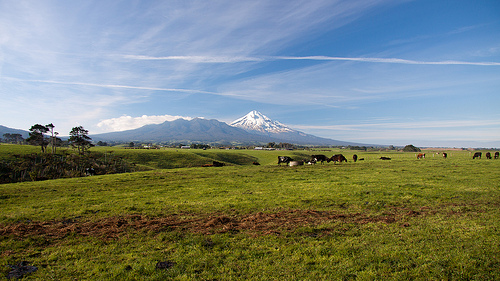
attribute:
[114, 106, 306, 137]
mountain — background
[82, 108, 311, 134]
mountain —  snow capped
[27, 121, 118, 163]
trees — background, Tall 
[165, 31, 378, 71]
clouds — Light colored , sky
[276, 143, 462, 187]
animals —  background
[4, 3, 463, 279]
photo — daytime,  outdoors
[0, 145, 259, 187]
hill — grassy, small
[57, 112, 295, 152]
mountain — brown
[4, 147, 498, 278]
grass — short, green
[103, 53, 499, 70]
line — white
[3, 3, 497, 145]
clouds — white, thin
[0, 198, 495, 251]
grass — brown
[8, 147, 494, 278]
field — wide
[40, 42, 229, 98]
cloud — white 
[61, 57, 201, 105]
cloud — white 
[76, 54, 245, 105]
cloud — white 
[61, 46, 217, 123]
cloud — white 